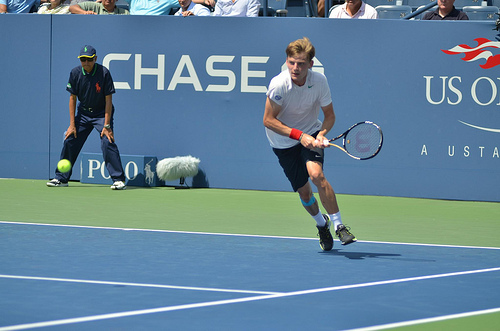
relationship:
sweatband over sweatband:
[287, 128, 302, 140] [287, 128, 302, 140]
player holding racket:
[259, 38, 356, 258] [306, 109, 417, 169]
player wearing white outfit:
[259, 38, 356, 258] [254, 74, 341, 149]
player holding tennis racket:
[259, 20, 395, 272] [310, 118, 385, 162]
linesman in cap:
[48, 40, 151, 201] [69, 38, 105, 59]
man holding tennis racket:
[261, 38, 370, 256] [321, 117, 392, 161]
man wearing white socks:
[261, 38, 370, 256] [309, 204, 346, 231]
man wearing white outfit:
[253, 32, 393, 264] [261, 74, 340, 145]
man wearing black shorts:
[261, 38, 370, 256] [264, 134, 340, 188]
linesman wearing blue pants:
[48, 45, 126, 192] [45, 111, 134, 180]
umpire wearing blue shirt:
[47, 35, 143, 193] [56, 62, 126, 119]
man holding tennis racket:
[253, 32, 393, 264] [310, 115, 390, 165]